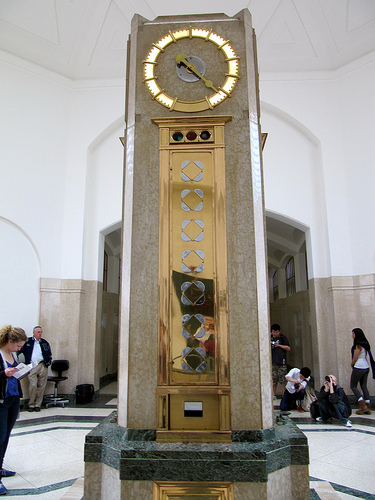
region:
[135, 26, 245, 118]
A clock face with light around the edges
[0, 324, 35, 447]
A woman reading a book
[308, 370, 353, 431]
A man taking a photograph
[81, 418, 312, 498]
Fine green and grey stone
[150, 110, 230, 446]
A golden piece of art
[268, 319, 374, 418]
A group of people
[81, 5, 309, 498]
A piece of art with a decorative clock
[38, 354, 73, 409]
A rolling chair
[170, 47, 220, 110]
The hand of a clock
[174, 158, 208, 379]
grey shapes on a golden background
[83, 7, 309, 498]
Tall tower with gold decoration and clock.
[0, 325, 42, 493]
Woman standing next to tower reading book.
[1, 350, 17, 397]
Woman dressed in blue top.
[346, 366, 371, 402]
Girl dressed in gray skinny jeans.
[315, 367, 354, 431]
Man squating down looking through camera.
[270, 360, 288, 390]
Man in background dressed in camouflage shorts.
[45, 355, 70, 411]
Black adjustable chair against wall in background.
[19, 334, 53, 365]
Man in background wearing navy blue jacket.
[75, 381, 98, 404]
Black trash bin sitting next to chair.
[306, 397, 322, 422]
Black bag sitting next to squatting man.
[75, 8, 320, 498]
a clock in the middle of the floor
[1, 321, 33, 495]
a lady looking at a pamphlet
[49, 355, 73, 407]
a black swivel chair against the wall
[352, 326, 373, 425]
this lady has leggings on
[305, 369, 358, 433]
a person squatting to take a picture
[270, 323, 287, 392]
this person has camo shorts on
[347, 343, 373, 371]
this lady has a white tank top on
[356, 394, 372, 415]
this lady has brown boots on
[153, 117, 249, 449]
the clock has brass fixtures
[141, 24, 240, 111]
the clock has lights around it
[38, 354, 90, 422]
A black and silver chair with wheels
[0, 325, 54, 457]
A woman in a blue shirt and black sweater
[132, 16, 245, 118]
The clock is gold and silver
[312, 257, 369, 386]
The walls are white and tan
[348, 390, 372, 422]
The woman is wearing brown boots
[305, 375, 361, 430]
The man is crouching down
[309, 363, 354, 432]
The man has a black camera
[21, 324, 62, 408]
A man with a black jacket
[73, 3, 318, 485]
The tower is silver, tan and gold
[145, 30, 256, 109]
The outer edges of the clock are lit up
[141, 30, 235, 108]
this is a clock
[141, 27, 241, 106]
the clock is glowing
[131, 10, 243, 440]
the stand is tall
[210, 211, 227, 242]
the metal is shiny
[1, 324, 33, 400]
this is a woman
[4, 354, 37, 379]
she is reading a magazine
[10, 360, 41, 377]
the magazine is white in color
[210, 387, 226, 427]
it is golden in color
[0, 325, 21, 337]
the hair is long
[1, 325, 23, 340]
the hair is brown in color